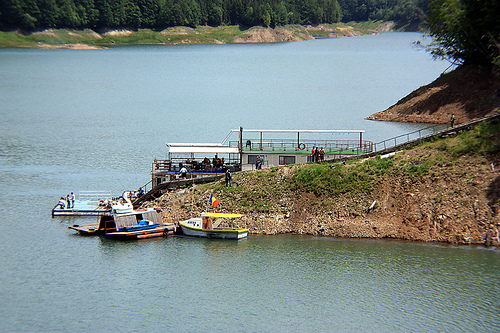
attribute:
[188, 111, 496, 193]
preserver — small, round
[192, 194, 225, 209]
flag — red, yellow, blue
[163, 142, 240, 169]
structure — full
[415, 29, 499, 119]
tree — large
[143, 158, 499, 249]
shoreline — grassy, rocky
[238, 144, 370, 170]
building — green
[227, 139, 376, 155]
rail — metal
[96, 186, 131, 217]
boat — small, white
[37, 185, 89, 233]
floating dock — light blue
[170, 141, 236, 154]
roof — white 